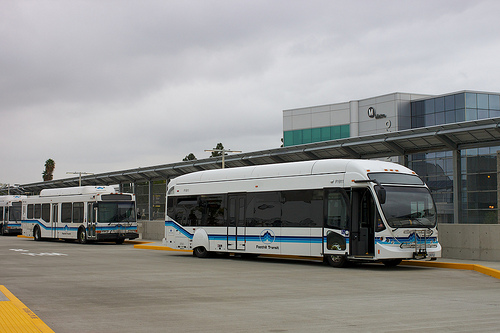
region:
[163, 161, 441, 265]
a large white blue striped bus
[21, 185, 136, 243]
a large white blue striped bus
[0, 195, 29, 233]
a large white blue striped bus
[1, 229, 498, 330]
a grey paved roadway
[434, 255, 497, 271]
a paved sidewalk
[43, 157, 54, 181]
a large tree in distance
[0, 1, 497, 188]
a cloudy white sky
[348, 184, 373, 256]
a passenger bus entry door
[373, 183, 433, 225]
a bus' glass windshield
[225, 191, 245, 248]
a bus' closed exit doors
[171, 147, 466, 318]
blue and white bus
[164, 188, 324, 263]
blue stripe on bus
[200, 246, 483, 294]
yellow stripe on curb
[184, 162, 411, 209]
bus top is white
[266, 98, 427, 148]
green and white building in distance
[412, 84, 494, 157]
building has reflective windows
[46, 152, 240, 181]
trees above bus station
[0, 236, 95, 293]
white writing on pavement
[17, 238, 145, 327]
pavement is dark grey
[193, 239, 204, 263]
bus wheels are black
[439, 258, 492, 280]
yellow curb along sidewalk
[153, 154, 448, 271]
bus setting at bus stop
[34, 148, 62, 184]
tree located behind transit station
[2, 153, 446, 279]
three white and blue buses at bus station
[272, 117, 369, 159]
green section of mostly gray building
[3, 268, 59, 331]
yellow road marking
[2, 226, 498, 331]
gray paved bus alley at transit station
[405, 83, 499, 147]
large section of windows on second story of building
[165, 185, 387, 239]
tinted windows running down side of bus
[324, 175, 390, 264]
open door of bus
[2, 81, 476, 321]
Buses parked by the building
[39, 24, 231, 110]
A heavily overcast sky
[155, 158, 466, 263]
A white and blue bus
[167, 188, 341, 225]
Large black windows on the bus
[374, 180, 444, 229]
The bus's front window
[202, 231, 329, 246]
Blue stripes on the bus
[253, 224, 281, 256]
A blue logo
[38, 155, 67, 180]
A green tree in the background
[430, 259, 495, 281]
A small yellow curb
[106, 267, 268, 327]
Grey concrete under the buses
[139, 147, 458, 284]
the bus is parked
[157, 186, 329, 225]
the windows on the bus are black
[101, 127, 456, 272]
the bus is white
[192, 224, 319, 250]
the bus has stripes on the side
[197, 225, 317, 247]
the stripes are blue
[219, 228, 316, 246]
there are 3 stripes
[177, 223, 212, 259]
the top of the wheel is covered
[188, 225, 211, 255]
the cover is white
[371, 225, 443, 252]
the headlights are off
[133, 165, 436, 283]
the bus is empty